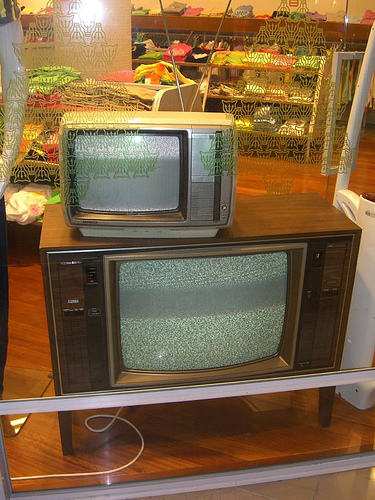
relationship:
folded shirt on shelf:
[183, 44, 212, 62] [132, 57, 322, 74]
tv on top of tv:
[63, 108, 236, 242] [40, 250, 357, 372]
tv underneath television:
[63, 108, 236, 242] [43, 189, 364, 460]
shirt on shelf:
[165, 40, 190, 62] [129, 48, 325, 78]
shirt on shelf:
[137, 50, 164, 60] [131, 49, 324, 73]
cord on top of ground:
[7, 412, 146, 478] [2, 125, 374, 498]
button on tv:
[219, 204, 228, 213] [53, 113, 208, 239]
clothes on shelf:
[61, 77, 161, 114] [0, 71, 207, 229]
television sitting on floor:
[95, 245, 307, 378] [100, 406, 330, 470]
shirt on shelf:
[309, 9, 330, 20] [128, 12, 374, 157]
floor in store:
[0, 150, 374, 488] [2, 3, 373, 498]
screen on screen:
[121, 254, 287, 367] [121, 254, 287, 367]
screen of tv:
[121, 254, 287, 367] [36, 190, 362, 457]